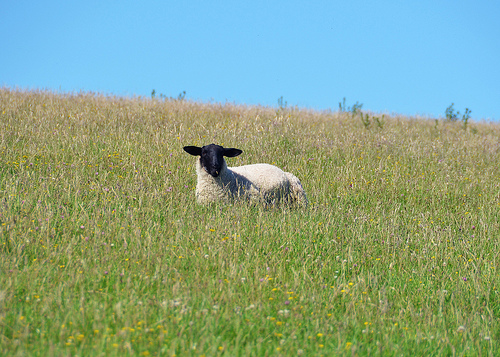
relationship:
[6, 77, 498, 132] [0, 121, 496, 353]
weeds rise above grass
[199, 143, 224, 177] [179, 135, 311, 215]
black face of goat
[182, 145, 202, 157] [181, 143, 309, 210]
ear on goat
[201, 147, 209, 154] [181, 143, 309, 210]
right eye on goat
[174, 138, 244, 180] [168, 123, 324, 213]
black head on sheep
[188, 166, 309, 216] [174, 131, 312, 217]
fur on sheep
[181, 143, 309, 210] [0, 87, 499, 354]
goat in grass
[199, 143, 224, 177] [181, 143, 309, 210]
black face on goat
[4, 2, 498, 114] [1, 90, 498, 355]
sky above field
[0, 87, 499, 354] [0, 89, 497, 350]
grass on hill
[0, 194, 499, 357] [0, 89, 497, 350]
flower on hill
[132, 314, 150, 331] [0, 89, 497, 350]
flower on hill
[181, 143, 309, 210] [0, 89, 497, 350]
goat on hill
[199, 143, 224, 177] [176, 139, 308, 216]
black face on sheep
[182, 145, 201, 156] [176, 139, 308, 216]
ear on sheep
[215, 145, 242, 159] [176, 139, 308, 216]
ear on sheep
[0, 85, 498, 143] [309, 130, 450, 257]
weeds protruding from grass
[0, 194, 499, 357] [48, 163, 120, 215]
flower in grass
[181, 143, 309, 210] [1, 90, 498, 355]
goat sitting in field